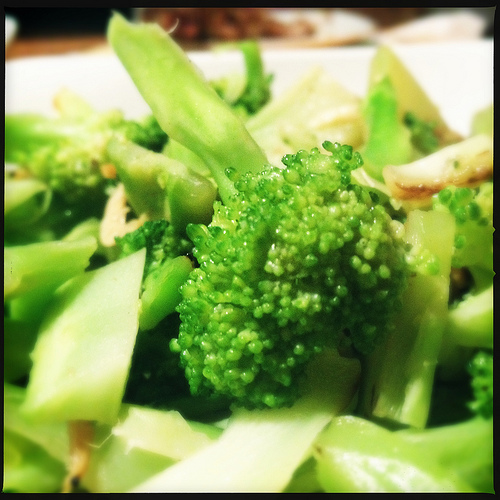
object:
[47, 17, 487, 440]
vegetables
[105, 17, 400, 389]
food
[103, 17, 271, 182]
broccoli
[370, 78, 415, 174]
stem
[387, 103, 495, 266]
vegetable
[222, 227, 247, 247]
grain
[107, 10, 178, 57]
out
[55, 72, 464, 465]
surface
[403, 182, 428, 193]
char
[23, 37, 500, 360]
cooking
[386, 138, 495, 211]
fry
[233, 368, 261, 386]
floret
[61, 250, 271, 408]
vegetables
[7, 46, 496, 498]
dish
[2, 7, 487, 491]
table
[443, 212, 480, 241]
ground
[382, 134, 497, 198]
onion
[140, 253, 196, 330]
broccoli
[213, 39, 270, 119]
broccoli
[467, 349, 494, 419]
broccoli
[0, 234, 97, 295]
broccoli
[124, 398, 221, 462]
stem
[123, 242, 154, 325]
sharp edge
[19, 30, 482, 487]
food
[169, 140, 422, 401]
broccoli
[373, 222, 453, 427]
broccoli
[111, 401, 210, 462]
broccoli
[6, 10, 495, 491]
meal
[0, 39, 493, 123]
dish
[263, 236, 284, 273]
buds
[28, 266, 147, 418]
spear